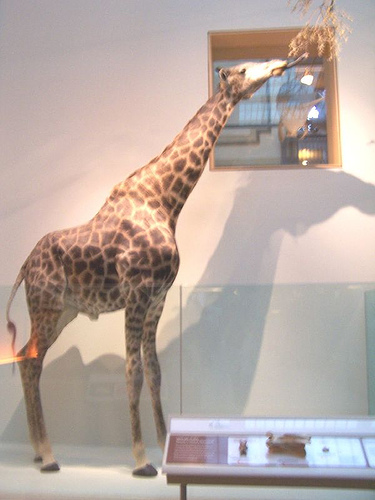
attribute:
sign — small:
[177, 415, 274, 486]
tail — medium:
[3, 274, 28, 372]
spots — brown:
[103, 228, 166, 263]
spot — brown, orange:
[87, 252, 105, 277]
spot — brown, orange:
[97, 228, 116, 245]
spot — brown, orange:
[148, 225, 167, 246]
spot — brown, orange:
[137, 181, 155, 199]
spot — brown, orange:
[170, 155, 187, 173]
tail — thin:
[0, 254, 30, 355]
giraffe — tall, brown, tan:
[12, 47, 328, 471]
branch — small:
[286, 6, 350, 60]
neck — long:
[114, 89, 240, 217]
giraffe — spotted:
[4, 48, 293, 483]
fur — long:
[79, 204, 149, 275]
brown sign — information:
[167, 433, 230, 464]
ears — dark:
[214, 65, 228, 82]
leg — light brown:
[141, 298, 179, 463]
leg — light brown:
[25, 285, 61, 470]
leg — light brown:
[16, 351, 42, 466]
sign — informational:
[169, 422, 374, 492]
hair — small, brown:
[10, 346, 18, 378]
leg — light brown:
[126, 285, 158, 479]